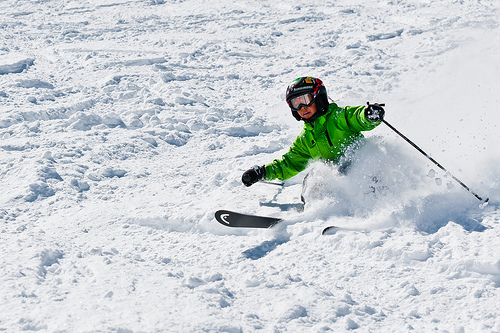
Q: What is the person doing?
A: Skiing.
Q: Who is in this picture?
A: A skier.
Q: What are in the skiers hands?
A: Ski poles.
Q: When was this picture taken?
A: Daytime.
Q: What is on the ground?
A: Snow.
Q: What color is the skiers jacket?
A: Green.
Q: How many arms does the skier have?
A: Two.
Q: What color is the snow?
A: White.